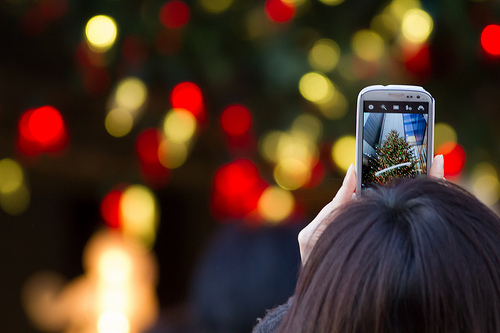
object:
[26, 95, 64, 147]
light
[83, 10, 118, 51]
lights